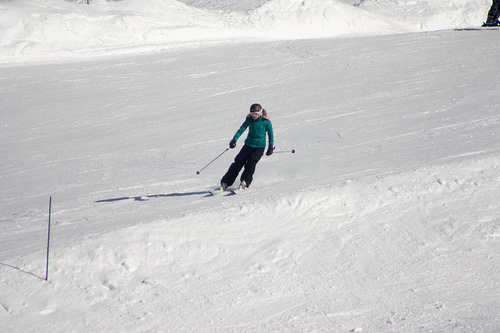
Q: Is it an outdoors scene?
A: Yes, it is outdoors.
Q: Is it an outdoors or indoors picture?
A: It is outdoors.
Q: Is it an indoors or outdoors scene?
A: It is outdoors.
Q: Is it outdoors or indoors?
A: It is outdoors.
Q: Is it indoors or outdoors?
A: It is outdoors.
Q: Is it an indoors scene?
A: No, it is outdoors.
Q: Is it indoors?
A: No, it is outdoors.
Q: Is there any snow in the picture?
A: Yes, there is snow.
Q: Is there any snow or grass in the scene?
A: Yes, there is snow.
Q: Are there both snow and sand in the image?
A: No, there is snow but no sand.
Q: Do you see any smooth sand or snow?
A: Yes, there is smooth snow.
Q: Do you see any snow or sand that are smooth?
A: Yes, the snow is smooth.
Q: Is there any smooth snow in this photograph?
A: Yes, there is smooth snow.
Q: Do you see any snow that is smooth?
A: Yes, there is snow that is smooth.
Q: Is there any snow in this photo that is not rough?
A: Yes, there is smooth snow.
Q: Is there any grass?
A: No, there is no grass.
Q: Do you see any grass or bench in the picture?
A: No, there are no grass or benches.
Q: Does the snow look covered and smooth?
A: Yes, the snow is covered and smooth.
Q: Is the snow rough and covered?
A: No, the snow is covered but smooth.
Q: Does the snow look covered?
A: Yes, the snow is covered.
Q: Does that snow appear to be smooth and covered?
A: Yes, the snow is smooth and covered.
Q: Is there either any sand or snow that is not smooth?
A: No, there is snow but it is smooth.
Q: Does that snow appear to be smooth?
A: Yes, the snow is smooth.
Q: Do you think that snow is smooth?
A: Yes, the snow is smooth.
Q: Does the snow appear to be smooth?
A: Yes, the snow is smooth.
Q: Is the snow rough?
A: No, the snow is smooth.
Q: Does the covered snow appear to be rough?
A: No, the snow is smooth.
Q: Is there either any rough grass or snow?
A: No, there is snow but it is smooth.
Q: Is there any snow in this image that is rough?
A: No, there is snow but it is smooth.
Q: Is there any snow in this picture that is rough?
A: No, there is snow but it is smooth.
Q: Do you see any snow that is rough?
A: No, there is snow but it is smooth.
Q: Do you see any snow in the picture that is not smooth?
A: No, there is snow but it is smooth.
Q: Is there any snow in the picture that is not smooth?
A: No, there is snow but it is smooth.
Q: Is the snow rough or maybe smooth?
A: The snow is smooth.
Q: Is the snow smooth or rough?
A: The snow is smooth.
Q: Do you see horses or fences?
A: No, there are no fences or horses.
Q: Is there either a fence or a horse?
A: No, there are no fences or horses.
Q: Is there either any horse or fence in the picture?
A: No, there are no fences or horses.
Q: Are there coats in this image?
A: Yes, there is a coat.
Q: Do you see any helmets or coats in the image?
A: Yes, there is a coat.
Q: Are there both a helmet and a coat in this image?
A: Yes, there are both a coat and a helmet.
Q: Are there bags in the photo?
A: No, there are no bags.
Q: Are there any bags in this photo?
A: No, there are no bags.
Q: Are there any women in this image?
A: Yes, there is a woman.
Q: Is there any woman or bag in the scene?
A: Yes, there is a woman.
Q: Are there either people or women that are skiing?
A: Yes, the woman is skiing.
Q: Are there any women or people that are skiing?
A: Yes, the woman is skiing.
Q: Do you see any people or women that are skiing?
A: Yes, the woman is skiing.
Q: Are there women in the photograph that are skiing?
A: Yes, there is a woman that is skiing.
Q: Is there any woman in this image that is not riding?
A: Yes, there is a woman that is skiing.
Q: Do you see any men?
A: No, there are no men.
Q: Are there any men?
A: No, there are no men.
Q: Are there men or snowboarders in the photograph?
A: No, there are no men or snowboarders.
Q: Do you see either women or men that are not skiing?
A: No, there is a woman but she is skiing.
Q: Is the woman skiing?
A: Yes, the woman is skiing.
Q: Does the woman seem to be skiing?
A: Yes, the woman is skiing.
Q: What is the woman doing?
A: The woman is skiing.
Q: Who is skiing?
A: The woman is skiing.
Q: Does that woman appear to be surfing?
A: No, the woman is skiing.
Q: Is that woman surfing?
A: No, the woman is skiing.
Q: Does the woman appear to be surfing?
A: No, the woman is skiing.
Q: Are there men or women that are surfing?
A: No, there is a woman but she is skiing.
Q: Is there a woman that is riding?
A: No, there is a woman but she is skiing.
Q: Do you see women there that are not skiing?
A: No, there is a woman but she is skiing.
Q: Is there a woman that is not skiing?
A: No, there is a woman but she is skiing.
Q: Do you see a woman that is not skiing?
A: No, there is a woman but she is skiing.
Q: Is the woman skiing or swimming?
A: The woman is skiing.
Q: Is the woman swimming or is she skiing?
A: The woman is skiing.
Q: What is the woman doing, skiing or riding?
A: The woman is skiing.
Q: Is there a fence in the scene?
A: No, there are no fences.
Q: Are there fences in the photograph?
A: No, there are no fences.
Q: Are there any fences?
A: No, there are no fences.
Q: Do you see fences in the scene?
A: No, there are no fences.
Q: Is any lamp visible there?
A: No, there are no lamps.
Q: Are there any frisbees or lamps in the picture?
A: No, there are no lamps or frisbees.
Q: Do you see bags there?
A: No, there are no bags.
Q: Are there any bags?
A: No, there are no bags.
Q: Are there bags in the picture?
A: No, there are no bags.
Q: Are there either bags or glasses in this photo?
A: No, there are no bags or glasses.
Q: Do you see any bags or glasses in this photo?
A: No, there are no bags or glasses.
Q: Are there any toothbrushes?
A: No, there are no toothbrushes.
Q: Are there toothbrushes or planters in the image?
A: No, there are no toothbrushes or planters.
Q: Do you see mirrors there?
A: No, there are no mirrors.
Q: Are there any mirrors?
A: No, there are no mirrors.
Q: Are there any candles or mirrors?
A: No, there are no mirrors or candles.